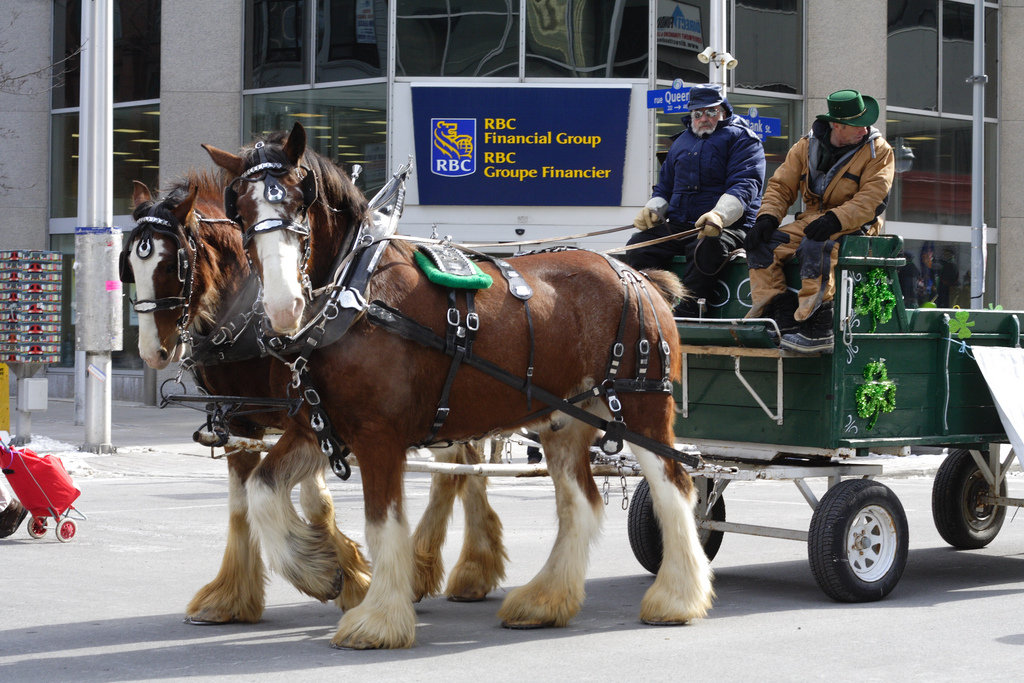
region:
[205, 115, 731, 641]
a horse walks down the street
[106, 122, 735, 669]
two horses walk down the road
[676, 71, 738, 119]
a man is wearing a blue hat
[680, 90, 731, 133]
a man wears sunglasses on his face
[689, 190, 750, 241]
man wears white gloves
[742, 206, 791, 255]
the man is wearing black gloves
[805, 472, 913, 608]
the wheel is black and round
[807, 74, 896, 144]
Man is wearing a hat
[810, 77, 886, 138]
Man is wearing a green hat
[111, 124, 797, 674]
Horses are pulling a wagon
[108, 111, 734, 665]
Horses are pulling a green wagon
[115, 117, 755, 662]
Brown and white horses pulling a wagon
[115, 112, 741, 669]
Brown and white horses pulling a green wagon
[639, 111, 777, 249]
Man is wearing a jacket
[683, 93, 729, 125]
Man is wearing sunglasses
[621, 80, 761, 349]
Man is sitting on a green wagon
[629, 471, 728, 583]
A tire on a vehicle.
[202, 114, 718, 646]
horse pulling a cart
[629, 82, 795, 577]
man in blue coat driving a cart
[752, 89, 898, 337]
man wearing a green hat riding in a cart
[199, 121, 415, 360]
a bridle on the horses neck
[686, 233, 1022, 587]
green shamrock on the side of the cart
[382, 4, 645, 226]
advertisement banner on a building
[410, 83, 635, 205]
blue sign with yellow letters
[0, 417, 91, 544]
an bag with white wheels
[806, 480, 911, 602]
white rim on the carts wheel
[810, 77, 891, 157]
Green hat on man's head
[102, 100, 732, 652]
Two brown horses side by side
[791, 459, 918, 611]
A black round wheel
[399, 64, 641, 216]
Yellow writing on a blue sign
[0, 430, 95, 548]
Red bag with two wheels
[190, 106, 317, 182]
Two pointy ears of a horse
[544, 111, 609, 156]
"Group" written on blue sign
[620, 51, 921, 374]
Two men sitting in a carriage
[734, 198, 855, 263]
A pair of black gloves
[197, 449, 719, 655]
the legs of the horses are white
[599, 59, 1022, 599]
two men on a cart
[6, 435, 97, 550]
a red bag with two wheels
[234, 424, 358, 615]
the leg is bend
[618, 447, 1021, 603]
the wheels of a cart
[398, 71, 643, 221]
a sign on a building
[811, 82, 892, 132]
the hat is color green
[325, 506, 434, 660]
the white leg is hairy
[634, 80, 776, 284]
man wears a blue coat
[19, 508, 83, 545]
the wheels are white and red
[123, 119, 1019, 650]
two horses pulling a green cart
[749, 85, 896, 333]
man wearing a green hat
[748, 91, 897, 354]
man wearing a brown jacket and black gloves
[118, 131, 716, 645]
two clydesdales in a parade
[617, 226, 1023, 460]
a green wagon with shamrocks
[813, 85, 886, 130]
man wearing a green hat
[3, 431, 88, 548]
shopping cart is red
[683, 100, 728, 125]
man is wearing sunglasses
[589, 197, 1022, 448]
wagon is emerald green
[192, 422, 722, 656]
horses have white legs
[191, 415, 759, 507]
metal pole to the wagon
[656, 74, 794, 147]
street signs are blue